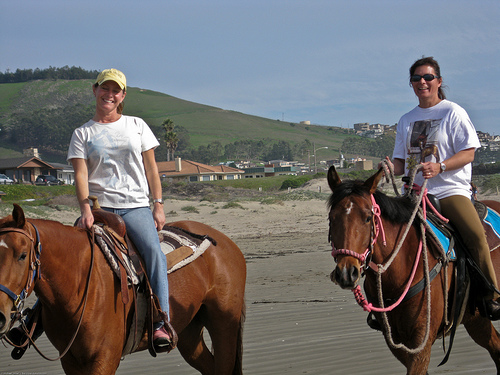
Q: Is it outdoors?
A: Yes, it is outdoors.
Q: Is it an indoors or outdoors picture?
A: It is outdoors.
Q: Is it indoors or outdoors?
A: It is outdoors.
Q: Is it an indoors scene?
A: No, it is outdoors.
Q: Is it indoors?
A: No, it is outdoors.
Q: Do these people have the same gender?
A: Yes, all the people are female.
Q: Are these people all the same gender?
A: Yes, all the people are female.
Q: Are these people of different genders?
A: No, all the people are female.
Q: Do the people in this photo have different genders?
A: No, all the people are female.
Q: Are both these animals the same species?
A: Yes, all the animals are horses.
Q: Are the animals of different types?
A: No, all the animals are horses.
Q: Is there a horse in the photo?
A: Yes, there is a horse.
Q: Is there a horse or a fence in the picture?
A: Yes, there is a horse.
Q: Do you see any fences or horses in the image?
A: Yes, there is a horse.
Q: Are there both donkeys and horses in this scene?
A: No, there is a horse but no donkeys.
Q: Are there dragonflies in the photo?
A: No, there are no dragonflies.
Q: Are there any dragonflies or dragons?
A: No, there are no dragonflies or dragons.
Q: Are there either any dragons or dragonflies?
A: No, there are no dragonflies or dragons.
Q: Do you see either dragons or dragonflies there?
A: No, there are no dragonflies or dragons.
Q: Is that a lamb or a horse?
A: That is a horse.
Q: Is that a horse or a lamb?
A: That is a horse.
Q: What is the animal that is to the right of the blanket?
A: The animal is a horse.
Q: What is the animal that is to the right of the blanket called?
A: The animal is a horse.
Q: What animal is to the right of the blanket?
A: The animal is a horse.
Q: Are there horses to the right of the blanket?
A: Yes, there is a horse to the right of the blanket.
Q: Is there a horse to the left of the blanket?
A: No, the horse is to the right of the blanket.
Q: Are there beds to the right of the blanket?
A: No, there is a horse to the right of the blanket.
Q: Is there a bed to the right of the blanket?
A: No, there is a horse to the right of the blanket.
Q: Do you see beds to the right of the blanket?
A: No, there is a horse to the right of the blanket.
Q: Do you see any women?
A: Yes, there is a woman.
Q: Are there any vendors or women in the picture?
A: Yes, there is a woman.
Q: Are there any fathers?
A: No, there are no fathers.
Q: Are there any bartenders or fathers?
A: No, there are no fathers or bartenders.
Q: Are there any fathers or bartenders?
A: No, there are no fathers or bartenders.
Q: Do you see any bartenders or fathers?
A: No, there are no fathers or bartenders.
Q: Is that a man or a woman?
A: That is a woman.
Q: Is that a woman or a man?
A: That is a woman.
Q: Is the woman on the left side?
A: Yes, the woman is on the left of the image.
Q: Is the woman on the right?
A: No, the woman is on the left of the image.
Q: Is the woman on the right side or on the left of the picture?
A: The woman is on the left of the image.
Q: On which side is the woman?
A: The woman is on the left of the image.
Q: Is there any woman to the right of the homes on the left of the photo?
A: Yes, there is a woman to the right of the homes.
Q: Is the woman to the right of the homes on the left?
A: Yes, the woman is to the right of the homes.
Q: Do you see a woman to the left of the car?
A: No, the woman is to the right of the car.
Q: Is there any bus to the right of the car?
A: No, there is a woman to the right of the car.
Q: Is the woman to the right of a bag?
A: No, the woman is to the right of the car.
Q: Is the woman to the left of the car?
A: No, the woman is to the right of the car.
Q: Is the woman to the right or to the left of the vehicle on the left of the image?
A: The woman is to the right of the car.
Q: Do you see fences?
A: No, there are no fences.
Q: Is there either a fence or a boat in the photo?
A: No, there are no fences or boats.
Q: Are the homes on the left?
A: Yes, the homes are on the left of the image.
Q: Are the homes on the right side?
A: No, the homes are on the left of the image.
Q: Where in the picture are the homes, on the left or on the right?
A: The homes are on the left of the image.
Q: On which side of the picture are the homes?
A: The homes are on the left of the image.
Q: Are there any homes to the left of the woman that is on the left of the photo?
A: Yes, there are homes to the left of the woman.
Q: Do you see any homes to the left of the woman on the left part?
A: Yes, there are homes to the left of the woman.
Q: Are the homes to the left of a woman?
A: Yes, the homes are to the left of a woman.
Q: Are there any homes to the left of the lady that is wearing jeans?
A: Yes, there are homes to the left of the lady.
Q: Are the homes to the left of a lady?
A: Yes, the homes are to the left of a lady.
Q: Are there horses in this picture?
A: Yes, there is a horse.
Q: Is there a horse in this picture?
A: Yes, there is a horse.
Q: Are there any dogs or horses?
A: Yes, there is a horse.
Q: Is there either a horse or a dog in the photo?
A: Yes, there is a horse.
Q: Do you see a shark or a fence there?
A: No, there are no fences or sharks.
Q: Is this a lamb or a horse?
A: This is a horse.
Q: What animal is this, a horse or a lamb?
A: This is a horse.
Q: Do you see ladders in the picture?
A: No, there are no ladders.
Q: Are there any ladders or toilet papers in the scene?
A: No, there are no ladders or toilet papers.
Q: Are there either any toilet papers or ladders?
A: No, there are no ladders or toilet papers.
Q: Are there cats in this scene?
A: No, there are no cats.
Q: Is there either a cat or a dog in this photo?
A: No, there are no cats or dogs.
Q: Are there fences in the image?
A: No, there are no fences.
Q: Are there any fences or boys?
A: No, there are no fences or boys.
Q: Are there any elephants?
A: No, there are no elephants.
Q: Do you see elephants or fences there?
A: No, there are no elephants or fences.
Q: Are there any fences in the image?
A: No, there are no fences.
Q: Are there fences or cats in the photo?
A: No, there are no fences or cats.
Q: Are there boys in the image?
A: No, there are no boys.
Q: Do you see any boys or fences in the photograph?
A: No, there are no boys or fences.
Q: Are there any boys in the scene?
A: No, there are no boys.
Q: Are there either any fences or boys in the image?
A: No, there are no boys or fences.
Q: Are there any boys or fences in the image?
A: No, there are no boys or fences.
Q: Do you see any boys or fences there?
A: No, there are no boys or fences.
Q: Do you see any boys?
A: No, there are no boys.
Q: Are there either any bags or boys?
A: No, there are no boys or bags.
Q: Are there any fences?
A: No, there are no fences.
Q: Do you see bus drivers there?
A: No, there are no bus drivers.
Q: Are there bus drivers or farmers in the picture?
A: No, there are no bus drivers or farmers.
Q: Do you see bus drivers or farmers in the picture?
A: No, there are no bus drivers or farmers.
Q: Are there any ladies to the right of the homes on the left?
A: Yes, there is a lady to the right of the homes.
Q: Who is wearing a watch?
A: The lady is wearing a watch.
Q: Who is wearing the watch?
A: The lady is wearing a watch.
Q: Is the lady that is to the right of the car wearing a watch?
A: Yes, the lady is wearing a watch.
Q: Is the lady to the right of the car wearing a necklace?
A: No, the lady is wearing a watch.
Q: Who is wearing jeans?
A: The lady is wearing jeans.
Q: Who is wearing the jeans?
A: The lady is wearing jeans.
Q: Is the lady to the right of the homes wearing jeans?
A: Yes, the lady is wearing jeans.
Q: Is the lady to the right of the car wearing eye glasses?
A: No, the lady is wearing jeans.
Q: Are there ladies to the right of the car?
A: Yes, there is a lady to the right of the car.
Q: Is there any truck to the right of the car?
A: No, there is a lady to the right of the car.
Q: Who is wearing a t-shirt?
A: The lady is wearing a t-shirt.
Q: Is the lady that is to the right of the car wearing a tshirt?
A: Yes, the lady is wearing a tshirt.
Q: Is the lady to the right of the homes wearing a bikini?
A: No, the lady is wearing a tshirt.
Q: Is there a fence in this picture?
A: No, there are no fences.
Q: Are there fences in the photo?
A: No, there are no fences.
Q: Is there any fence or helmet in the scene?
A: No, there are no fences or helmets.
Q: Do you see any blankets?
A: Yes, there is a blanket.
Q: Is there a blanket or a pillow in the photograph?
A: Yes, there is a blanket.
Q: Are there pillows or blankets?
A: Yes, there is a blanket.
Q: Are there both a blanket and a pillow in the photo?
A: No, there is a blanket but no pillows.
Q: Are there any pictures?
A: No, there are no pictures.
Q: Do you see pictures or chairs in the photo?
A: No, there are no pictures or chairs.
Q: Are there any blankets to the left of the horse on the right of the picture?
A: Yes, there is a blanket to the left of the horse.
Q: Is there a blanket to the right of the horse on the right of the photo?
A: No, the blanket is to the left of the horse.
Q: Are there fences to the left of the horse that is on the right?
A: No, there is a blanket to the left of the horse.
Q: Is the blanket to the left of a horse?
A: Yes, the blanket is to the left of a horse.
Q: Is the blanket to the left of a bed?
A: No, the blanket is to the left of a horse.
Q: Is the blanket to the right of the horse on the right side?
A: No, the blanket is to the left of the horse.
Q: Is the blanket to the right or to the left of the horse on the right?
A: The blanket is to the left of the horse.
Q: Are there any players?
A: No, there are no players.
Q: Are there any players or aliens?
A: No, there are no players or aliens.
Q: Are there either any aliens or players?
A: No, there are no players or aliens.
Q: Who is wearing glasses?
A: The lady is wearing glasses.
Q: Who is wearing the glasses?
A: The lady is wearing glasses.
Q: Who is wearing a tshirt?
A: The lady is wearing a tshirt.